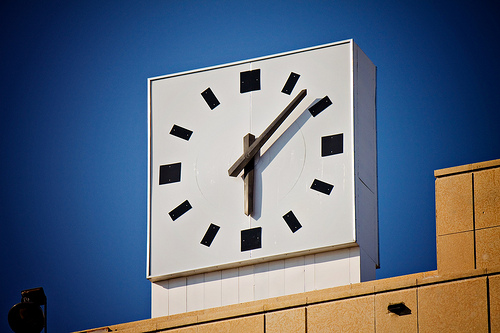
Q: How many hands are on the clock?
A: Two.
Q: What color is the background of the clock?
A: White.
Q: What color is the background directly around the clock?
A: Light blue.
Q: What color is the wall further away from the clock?
A: Dark blue.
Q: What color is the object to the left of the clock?
A: Black.